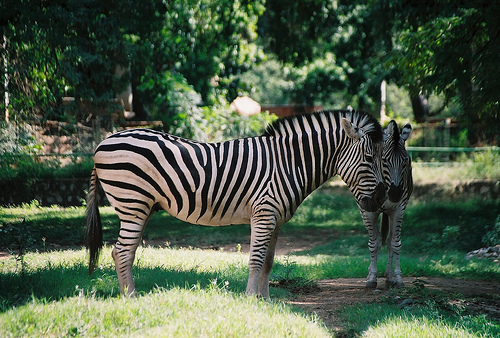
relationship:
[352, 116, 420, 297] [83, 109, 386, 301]
zebra standing beside zebra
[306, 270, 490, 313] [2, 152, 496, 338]
dirt in grass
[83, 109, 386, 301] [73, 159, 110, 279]
zebra has tail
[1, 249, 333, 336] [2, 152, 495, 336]
sunlight on grass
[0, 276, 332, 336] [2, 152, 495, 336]
spot on grass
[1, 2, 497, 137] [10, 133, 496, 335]
trees over area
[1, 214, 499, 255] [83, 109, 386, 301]
shade behind zebra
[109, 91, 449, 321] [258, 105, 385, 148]
zebra has mane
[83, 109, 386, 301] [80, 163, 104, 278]
zebra has tail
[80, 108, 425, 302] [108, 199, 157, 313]
zebra has leg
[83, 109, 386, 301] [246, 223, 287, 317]
zebra has leg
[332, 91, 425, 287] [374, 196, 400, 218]
zebra has nose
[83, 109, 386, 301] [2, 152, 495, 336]
zebra standing on grass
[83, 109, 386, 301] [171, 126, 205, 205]
zebra has black stripes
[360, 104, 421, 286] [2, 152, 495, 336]
zebra standing on grass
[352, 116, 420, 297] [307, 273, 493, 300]
zebra standing on dirt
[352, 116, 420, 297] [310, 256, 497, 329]
zebra standing in shade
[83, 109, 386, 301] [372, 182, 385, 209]
zebra has nose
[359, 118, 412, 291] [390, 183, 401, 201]
zebra has nose